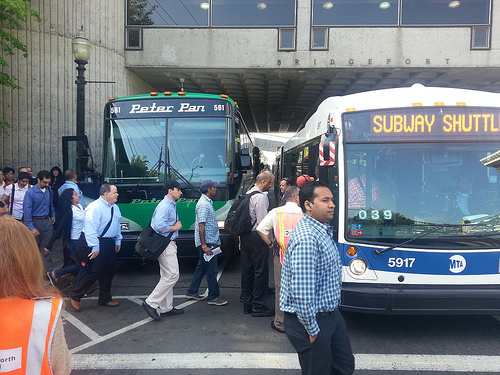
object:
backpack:
[224, 187, 264, 239]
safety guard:
[1, 210, 75, 375]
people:
[74, 184, 126, 309]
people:
[48, 188, 88, 281]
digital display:
[372, 110, 500, 135]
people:
[236, 167, 280, 318]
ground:
[0, 312, 500, 375]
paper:
[202, 247, 222, 263]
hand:
[114, 243, 121, 253]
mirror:
[317, 128, 337, 165]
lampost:
[72, 62, 92, 174]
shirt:
[279, 216, 343, 330]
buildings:
[102, 2, 500, 92]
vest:
[0, 290, 69, 375]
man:
[188, 178, 230, 307]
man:
[133, 179, 185, 320]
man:
[69, 182, 121, 313]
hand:
[307, 332, 321, 343]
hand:
[176, 221, 183, 230]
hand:
[202, 244, 213, 255]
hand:
[88, 250, 100, 260]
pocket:
[304, 334, 322, 354]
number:
[355, 208, 368, 221]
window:
[344, 141, 499, 230]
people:
[22, 170, 57, 269]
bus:
[96, 91, 256, 260]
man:
[279, 180, 354, 373]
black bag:
[71, 231, 95, 265]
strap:
[98, 205, 115, 239]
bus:
[265, 83, 496, 322]